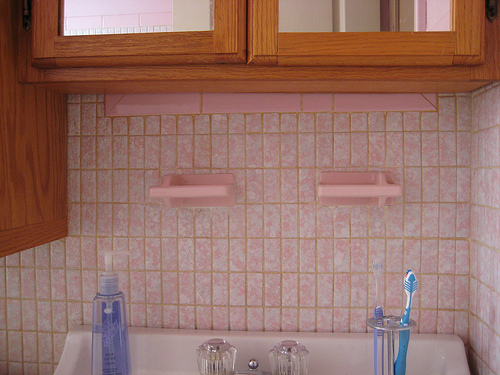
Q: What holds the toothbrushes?
A: Toothbrush holder.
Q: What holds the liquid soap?
A: Soap dispenser.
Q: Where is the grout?
A: Between the tile.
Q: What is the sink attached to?
A: The wall.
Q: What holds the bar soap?
A: The soap holder.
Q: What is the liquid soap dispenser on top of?
A: The sink.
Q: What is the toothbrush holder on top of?
A: The sink.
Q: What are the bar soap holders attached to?
A: The wall.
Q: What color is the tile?
A: Pink and white.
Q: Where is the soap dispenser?
A: Left of sink.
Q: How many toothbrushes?
A: 2.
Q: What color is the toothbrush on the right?
A: Blue.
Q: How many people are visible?
A: Zero.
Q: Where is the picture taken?
A: Bathroom.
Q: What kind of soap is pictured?
A: Liquid.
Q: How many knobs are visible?
A: 2.